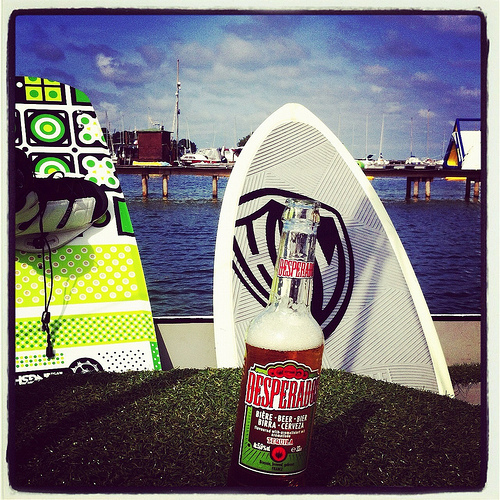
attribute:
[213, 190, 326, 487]
bottle — glass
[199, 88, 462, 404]
surfboard — white, black, black gray, green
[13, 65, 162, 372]
surfboard — brightly decorated, very bright, colorful, green, white, yellow, black, neon green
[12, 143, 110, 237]
shoe — black, white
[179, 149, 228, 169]
boat — red, white, moored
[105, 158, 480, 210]
pier — wooden, long, brown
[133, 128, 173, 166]
building — small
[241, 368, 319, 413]
label — red, white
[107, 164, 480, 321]
water — blue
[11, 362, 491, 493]
grass — fake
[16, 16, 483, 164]
sky — blue, cloudy, white